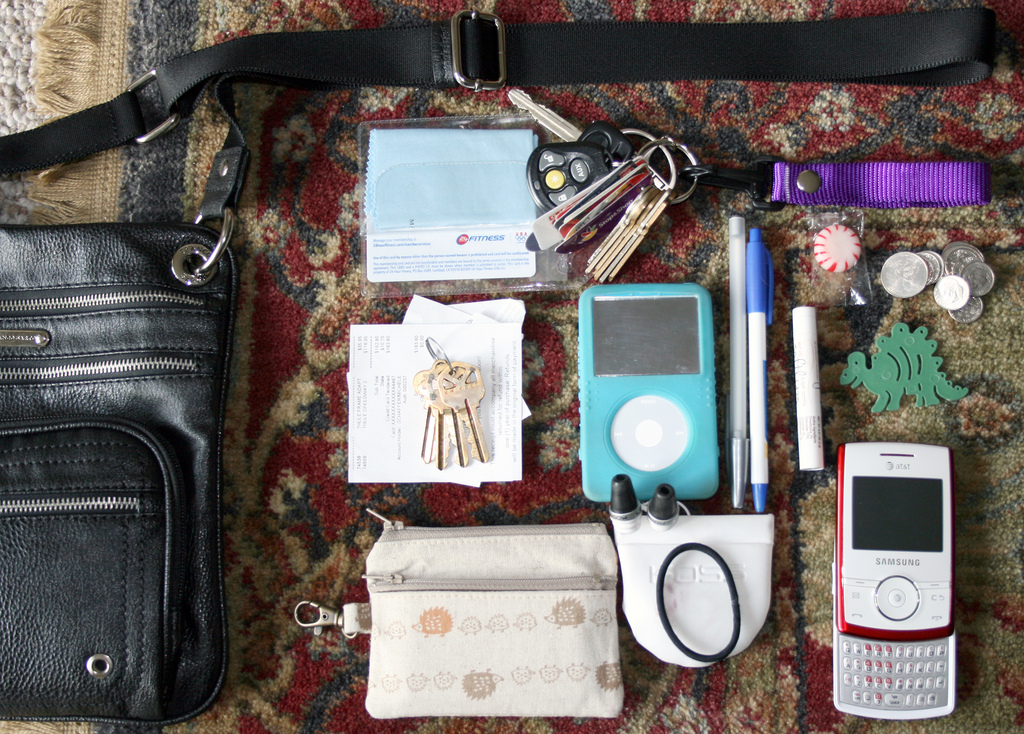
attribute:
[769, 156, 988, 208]
thing — purple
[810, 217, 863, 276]
mint — red, white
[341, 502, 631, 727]
coin purse — white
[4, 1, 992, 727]
crossbody bag — black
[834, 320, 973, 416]
dinosaur stencil — green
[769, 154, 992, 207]
wrist strap — purple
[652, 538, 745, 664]
hair tie — black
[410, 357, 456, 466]
key — gold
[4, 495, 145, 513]
zipper — closed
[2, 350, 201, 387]
zipper — closed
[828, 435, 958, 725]
cell phone — candy bar style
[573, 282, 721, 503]
ipod — classic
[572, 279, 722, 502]
case — blue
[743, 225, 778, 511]
ballpoint pen — blue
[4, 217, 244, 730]
purse — black, leather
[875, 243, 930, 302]
coin — silver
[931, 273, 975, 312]
coin — silver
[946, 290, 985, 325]
coin — silver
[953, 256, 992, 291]
coin — silver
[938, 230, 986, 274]
coin — silver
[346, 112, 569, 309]
lanyard — plastic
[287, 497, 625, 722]
pouch — small, tan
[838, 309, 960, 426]
item — on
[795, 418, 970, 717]
item — on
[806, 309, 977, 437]
item — on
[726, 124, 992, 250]
item — on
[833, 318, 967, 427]
item — on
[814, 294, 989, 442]
item — on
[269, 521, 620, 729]
wallet — white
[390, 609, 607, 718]
design — hedgehog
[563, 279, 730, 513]
ipod — blue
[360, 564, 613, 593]
zipper — gray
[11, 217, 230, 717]
bag — black, leather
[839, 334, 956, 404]
air freshener — green, dinosaur shaped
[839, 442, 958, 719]
cellphone — white, red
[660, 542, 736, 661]
rubber band — small, black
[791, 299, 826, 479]
chalk stick — white